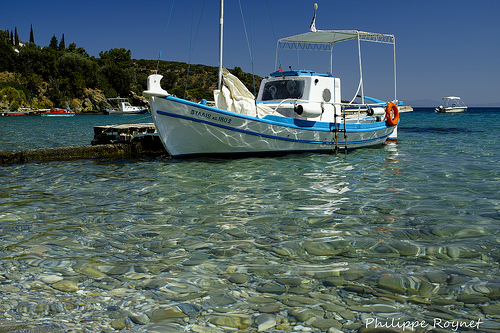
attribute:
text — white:
[363, 316, 369, 330]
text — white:
[358, 294, 383, 324]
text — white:
[362, 305, 403, 323]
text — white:
[395, 311, 405, 331]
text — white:
[405, 319, 406, 329]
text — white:
[411, 304, 434, 322]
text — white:
[423, 308, 457, 328]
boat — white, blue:
[94, 13, 432, 188]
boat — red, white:
[35, 94, 104, 144]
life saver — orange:
[372, 76, 393, 125]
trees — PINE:
[35, 37, 135, 82]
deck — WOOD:
[90, 119, 148, 144]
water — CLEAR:
[18, 130, 451, 330]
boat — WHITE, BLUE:
[135, 21, 405, 157]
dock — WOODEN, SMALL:
[88, 119, 151, 149]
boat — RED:
[37, 104, 77, 117]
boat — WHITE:
[431, 92, 471, 119]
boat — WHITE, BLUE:
[139, 19, 402, 170]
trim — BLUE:
[162, 96, 402, 133]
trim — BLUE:
[273, 67, 334, 78]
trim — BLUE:
[159, 108, 390, 148]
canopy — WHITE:
[274, 14, 394, 106]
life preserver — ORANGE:
[383, 101, 400, 123]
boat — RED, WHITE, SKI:
[43, 104, 75, 120]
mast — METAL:
[209, 9, 227, 103]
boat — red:
[0, 99, 80, 119]